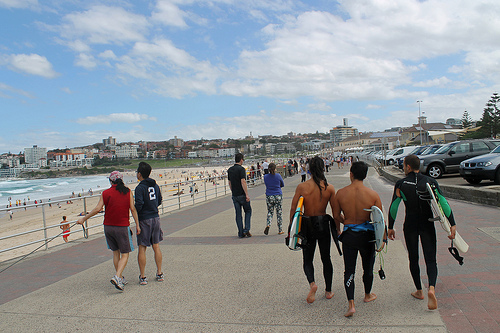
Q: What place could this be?
A: It is a street.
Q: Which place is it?
A: It is a street.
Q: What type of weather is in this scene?
A: It is partly cloudy.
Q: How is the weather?
A: It is partly cloudy.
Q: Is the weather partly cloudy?
A: Yes, it is partly cloudy.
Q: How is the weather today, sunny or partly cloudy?
A: It is partly cloudy.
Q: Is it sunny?
A: No, it is partly cloudy.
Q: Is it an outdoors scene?
A: Yes, it is outdoors.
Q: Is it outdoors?
A: Yes, it is outdoors.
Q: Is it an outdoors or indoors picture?
A: It is outdoors.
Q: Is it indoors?
A: No, it is outdoors.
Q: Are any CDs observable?
A: No, there are no cds.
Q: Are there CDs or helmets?
A: No, there are no CDs or helmets.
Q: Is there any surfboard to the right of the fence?
A: Yes, there are surfboards to the right of the fence.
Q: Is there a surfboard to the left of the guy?
A: Yes, there are surfboards to the left of the guy.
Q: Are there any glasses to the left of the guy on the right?
A: No, there are surfboards to the left of the guy.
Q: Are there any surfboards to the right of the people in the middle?
A: Yes, there are surfboards to the right of the people.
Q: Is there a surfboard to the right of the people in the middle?
A: Yes, there are surfboards to the right of the people.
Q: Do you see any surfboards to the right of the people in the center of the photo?
A: Yes, there are surfboards to the right of the people.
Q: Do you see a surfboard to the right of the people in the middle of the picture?
A: Yes, there are surfboards to the right of the people.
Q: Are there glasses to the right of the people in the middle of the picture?
A: No, there are surfboards to the right of the people.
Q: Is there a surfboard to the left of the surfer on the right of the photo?
A: Yes, there are surfboards to the left of the surfer.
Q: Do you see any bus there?
A: No, there are no buses.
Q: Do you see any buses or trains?
A: No, there are no buses or trains.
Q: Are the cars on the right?
A: Yes, the cars are on the right of the image.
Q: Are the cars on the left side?
A: No, the cars are on the right of the image.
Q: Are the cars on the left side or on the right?
A: The cars are on the right of the image.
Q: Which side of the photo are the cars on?
A: The cars are on the right of the image.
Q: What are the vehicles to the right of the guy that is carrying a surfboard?
A: The vehicles are cars.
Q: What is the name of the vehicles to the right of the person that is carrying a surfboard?
A: The vehicles are cars.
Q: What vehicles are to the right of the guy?
A: The vehicles are cars.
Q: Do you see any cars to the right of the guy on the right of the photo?
A: Yes, there are cars to the right of the guy.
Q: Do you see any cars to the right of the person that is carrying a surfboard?
A: Yes, there are cars to the right of the guy.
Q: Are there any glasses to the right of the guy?
A: No, there are cars to the right of the guy.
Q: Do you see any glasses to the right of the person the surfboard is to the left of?
A: No, there are cars to the right of the guy.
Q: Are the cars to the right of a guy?
A: Yes, the cars are to the right of a guy.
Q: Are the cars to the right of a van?
A: No, the cars are to the right of a guy.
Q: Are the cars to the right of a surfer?
A: Yes, the cars are to the right of a surfer.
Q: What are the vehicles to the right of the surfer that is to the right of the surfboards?
A: The vehicles are cars.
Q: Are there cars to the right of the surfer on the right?
A: Yes, there are cars to the right of the surfer.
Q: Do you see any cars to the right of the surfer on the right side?
A: Yes, there are cars to the right of the surfer.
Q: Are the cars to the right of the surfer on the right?
A: Yes, the cars are to the right of the surfer.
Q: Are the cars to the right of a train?
A: No, the cars are to the right of the surfer.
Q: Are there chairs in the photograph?
A: No, there are no chairs.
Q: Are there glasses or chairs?
A: No, there are no chairs or glasses.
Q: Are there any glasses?
A: No, there are no glasses.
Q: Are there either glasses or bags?
A: No, there are no glasses or bags.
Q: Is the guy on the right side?
A: Yes, the guy is on the right of the image.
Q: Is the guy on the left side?
A: No, the guy is on the right of the image.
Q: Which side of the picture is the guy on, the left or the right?
A: The guy is on the right of the image.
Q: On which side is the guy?
A: The guy is on the right of the image.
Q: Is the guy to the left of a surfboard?
A: No, the guy is to the right of a surfboard.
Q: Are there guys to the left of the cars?
A: Yes, there is a guy to the left of the cars.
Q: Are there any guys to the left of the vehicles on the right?
A: Yes, there is a guy to the left of the cars.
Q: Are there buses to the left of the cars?
A: No, there is a guy to the left of the cars.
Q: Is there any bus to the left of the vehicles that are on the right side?
A: No, there is a guy to the left of the cars.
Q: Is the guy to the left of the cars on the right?
A: Yes, the guy is to the left of the cars.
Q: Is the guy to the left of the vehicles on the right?
A: Yes, the guy is to the left of the cars.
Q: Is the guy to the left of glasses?
A: No, the guy is to the left of the cars.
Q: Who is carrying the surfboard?
A: The guy is carrying the surfboard.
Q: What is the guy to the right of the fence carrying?
A: The guy is carrying a surfboard.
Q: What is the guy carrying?
A: The guy is carrying a surfboard.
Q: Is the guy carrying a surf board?
A: Yes, the guy is carrying a surf board.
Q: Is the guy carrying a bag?
A: No, the guy is carrying a surf board.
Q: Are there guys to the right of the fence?
A: Yes, there is a guy to the right of the fence.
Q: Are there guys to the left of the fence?
A: No, the guy is to the right of the fence.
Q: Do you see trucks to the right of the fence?
A: No, there is a guy to the right of the fence.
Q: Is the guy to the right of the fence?
A: Yes, the guy is to the right of the fence.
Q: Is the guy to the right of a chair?
A: No, the guy is to the right of the fence.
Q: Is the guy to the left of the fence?
A: No, the guy is to the right of the fence.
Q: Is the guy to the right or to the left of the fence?
A: The guy is to the right of the fence.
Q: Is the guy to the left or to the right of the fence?
A: The guy is to the right of the fence.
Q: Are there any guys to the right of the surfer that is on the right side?
A: Yes, there is a guy to the right of the surfer.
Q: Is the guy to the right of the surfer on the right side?
A: Yes, the guy is to the right of the surfer.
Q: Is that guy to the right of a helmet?
A: No, the guy is to the right of the surfer.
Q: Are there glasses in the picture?
A: No, there are no glasses.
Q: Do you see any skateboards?
A: No, there are no skateboards.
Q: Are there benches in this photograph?
A: No, there are no benches.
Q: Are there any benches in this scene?
A: No, there are no benches.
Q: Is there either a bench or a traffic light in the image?
A: No, there are no benches or traffic lights.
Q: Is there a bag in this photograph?
A: No, there are no bags.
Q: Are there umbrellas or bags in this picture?
A: No, there are no bags or umbrellas.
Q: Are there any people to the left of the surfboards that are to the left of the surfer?
A: Yes, there are people to the left of the surfboards.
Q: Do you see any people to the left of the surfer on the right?
A: Yes, there are people to the left of the surfer.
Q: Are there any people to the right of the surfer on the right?
A: No, the people are to the left of the surfer.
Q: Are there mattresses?
A: No, there are no mattresses.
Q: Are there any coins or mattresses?
A: No, there are no mattresses or coins.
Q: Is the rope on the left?
A: Yes, the rope is on the left of the image.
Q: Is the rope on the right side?
A: No, the rope is on the left of the image.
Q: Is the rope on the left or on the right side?
A: The rope is on the left of the image.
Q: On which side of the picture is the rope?
A: The rope is on the left of the image.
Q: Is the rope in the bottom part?
A: Yes, the rope is in the bottom of the image.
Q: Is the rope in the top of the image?
A: No, the rope is in the bottom of the image.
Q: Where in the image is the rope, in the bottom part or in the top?
A: The rope is in the bottom of the image.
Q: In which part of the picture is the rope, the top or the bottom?
A: The rope is in the bottom of the image.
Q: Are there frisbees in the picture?
A: No, there are no frisbees.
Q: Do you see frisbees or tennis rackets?
A: No, there are no frisbees or tennis rackets.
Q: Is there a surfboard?
A: Yes, there is a surfboard.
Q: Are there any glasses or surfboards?
A: Yes, there is a surfboard.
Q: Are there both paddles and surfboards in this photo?
A: No, there is a surfboard but no paddles.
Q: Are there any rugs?
A: No, there are no rugs.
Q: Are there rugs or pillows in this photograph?
A: No, there are no rugs or pillows.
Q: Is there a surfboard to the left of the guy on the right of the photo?
A: Yes, there is a surfboard to the left of the guy.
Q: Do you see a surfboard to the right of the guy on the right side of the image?
A: No, the surfboard is to the left of the guy.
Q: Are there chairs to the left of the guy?
A: No, there is a surfboard to the left of the guy.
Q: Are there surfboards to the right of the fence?
A: Yes, there is a surfboard to the right of the fence.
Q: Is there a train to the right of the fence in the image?
A: No, there is a surfboard to the right of the fence.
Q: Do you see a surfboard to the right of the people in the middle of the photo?
A: Yes, there is a surfboard to the right of the people.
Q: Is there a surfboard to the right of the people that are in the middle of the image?
A: Yes, there is a surfboard to the right of the people.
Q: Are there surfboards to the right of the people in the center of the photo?
A: Yes, there is a surfboard to the right of the people.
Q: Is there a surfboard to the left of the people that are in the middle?
A: No, the surfboard is to the right of the people.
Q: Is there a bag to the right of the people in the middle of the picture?
A: No, there is a surfboard to the right of the people.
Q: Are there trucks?
A: No, there are no trucks.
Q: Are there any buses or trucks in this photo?
A: No, there are no trucks or buses.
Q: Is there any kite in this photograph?
A: No, there are no kites.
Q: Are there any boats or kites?
A: No, there are no kites or boats.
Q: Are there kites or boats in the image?
A: No, there are no kites or boats.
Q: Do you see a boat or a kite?
A: No, there are no kites or boats.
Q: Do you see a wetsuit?
A: Yes, there is a wetsuit.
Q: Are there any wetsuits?
A: Yes, there is a wetsuit.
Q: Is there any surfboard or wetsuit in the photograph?
A: Yes, there is a wetsuit.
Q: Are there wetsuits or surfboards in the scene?
A: Yes, there is a wetsuit.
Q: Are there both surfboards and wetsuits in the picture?
A: Yes, there are both a wetsuit and a surfboard.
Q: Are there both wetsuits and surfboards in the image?
A: Yes, there are both a wetsuit and a surfboard.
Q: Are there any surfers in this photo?
A: Yes, there is a surfer.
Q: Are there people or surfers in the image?
A: Yes, there is a surfer.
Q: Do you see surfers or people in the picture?
A: Yes, there is a surfer.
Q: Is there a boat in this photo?
A: No, there are no boats.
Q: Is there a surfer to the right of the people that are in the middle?
A: Yes, there is a surfer to the right of the people.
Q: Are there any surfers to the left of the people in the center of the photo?
A: No, the surfer is to the right of the people.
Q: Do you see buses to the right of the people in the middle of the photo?
A: No, there is a surfer to the right of the people.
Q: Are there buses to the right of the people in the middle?
A: No, there is a surfer to the right of the people.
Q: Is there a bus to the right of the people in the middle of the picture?
A: No, there is a surfer to the right of the people.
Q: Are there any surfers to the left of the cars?
A: Yes, there is a surfer to the left of the cars.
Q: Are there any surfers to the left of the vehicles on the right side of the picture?
A: Yes, there is a surfer to the left of the cars.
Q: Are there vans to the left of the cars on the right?
A: No, there is a surfer to the left of the cars.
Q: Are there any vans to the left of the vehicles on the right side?
A: No, there is a surfer to the left of the cars.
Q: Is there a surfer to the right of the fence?
A: Yes, there is a surfer to the right of the fence.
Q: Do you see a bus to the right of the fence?
A: No, there is a surfer to the right of the fence.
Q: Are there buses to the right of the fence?
A: No, there is a surfer to the right of the fence.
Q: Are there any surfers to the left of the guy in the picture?
A: Yes, there is a surfer to the left of the guy.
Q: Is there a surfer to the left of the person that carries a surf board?
A: Yes, there is a surfer to the left of the guy.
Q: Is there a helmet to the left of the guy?
A: No, there is a surfer to the left of the guy.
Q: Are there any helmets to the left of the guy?
A: No, there is a surfer to the left of the guy.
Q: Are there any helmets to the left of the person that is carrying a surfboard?
A: No, there is a surfer to the left of the guy.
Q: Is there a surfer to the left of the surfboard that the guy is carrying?
A: Yes, there is a surfer to the left of the surf board.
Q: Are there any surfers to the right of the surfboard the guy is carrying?
A: No, the surfer is to the left of the surf board.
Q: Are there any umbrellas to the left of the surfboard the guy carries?
A: No, there is a surfer to the left of the surfboard.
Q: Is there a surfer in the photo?
A: Yes, there is a surfer.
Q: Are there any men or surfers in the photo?
A: Yes, there is a surfer.